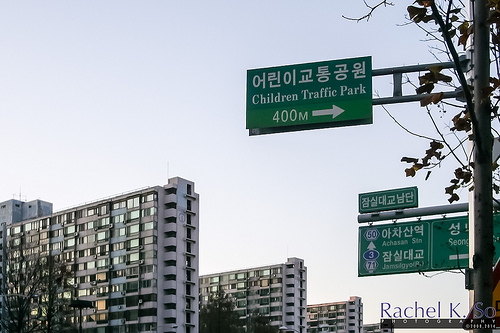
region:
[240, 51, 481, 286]
Green and white street signs.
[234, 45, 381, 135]
The sign is written in more than one language.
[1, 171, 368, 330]
Three buildings in a row.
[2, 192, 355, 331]
Windows on the buildings.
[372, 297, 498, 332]
The photographers name is listed in the bottom right corner.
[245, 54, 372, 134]
green sign with white writing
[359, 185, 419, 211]
green sign with white writing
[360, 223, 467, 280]
green sign with white writing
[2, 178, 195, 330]
tall white building with windows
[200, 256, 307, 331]
tall white building with windows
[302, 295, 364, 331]
tall white building with windows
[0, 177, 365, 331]
three tall white building with windows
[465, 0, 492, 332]
trunk of a skinny tree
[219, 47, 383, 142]
children traffic park sign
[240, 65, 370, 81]
chinese language on the sign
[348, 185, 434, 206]
chinese language on the sign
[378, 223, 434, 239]
chinese language on the sign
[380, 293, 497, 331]
rachel K so photography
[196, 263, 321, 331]
white apartment building in the distance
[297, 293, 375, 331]
white apartment building in the distance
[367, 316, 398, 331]
white apartment building in the distance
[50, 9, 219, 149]
beautiful blue sky for the day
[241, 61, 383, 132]
green and white highway sign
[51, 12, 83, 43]
white clouds in blue sky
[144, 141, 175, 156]
white clouds in blue sky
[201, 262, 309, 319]
white building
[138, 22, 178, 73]
white clouds in blue sky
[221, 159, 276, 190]
white clouds in blue sky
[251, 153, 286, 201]
white clouds in blue sky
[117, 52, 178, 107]
white clouds in blue sky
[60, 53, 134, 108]
white clouds in blue sky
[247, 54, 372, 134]
green and white sign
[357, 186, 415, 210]
sign is on a pole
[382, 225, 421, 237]
the writing is Asian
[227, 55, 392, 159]
a sign that is green in color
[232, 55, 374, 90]
writing that is written in korean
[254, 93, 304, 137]
a number that is white in color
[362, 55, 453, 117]
a pole that is grey in color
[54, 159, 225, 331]
an apartment building that is tall and white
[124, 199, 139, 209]
A window on a building.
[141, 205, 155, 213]
A window on a building.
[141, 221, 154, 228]
A window on a building.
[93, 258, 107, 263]
A window on a building.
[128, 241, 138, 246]
A window on a building.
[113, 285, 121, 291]
A window on a building.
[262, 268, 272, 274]
A window on a building.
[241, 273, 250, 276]
A window on a building.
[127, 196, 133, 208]
windown on large residential building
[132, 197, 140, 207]
windown on large residential building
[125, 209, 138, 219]
windown on large residential building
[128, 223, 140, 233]
windown on large residential building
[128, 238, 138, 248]
windown on large residential building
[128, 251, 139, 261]
windown on large residential building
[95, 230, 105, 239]
windown on large residential building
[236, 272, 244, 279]
windown on large residential building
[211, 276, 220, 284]
windown on large residential building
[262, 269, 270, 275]
windown on large residential building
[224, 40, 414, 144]
green and white sign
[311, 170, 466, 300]
sign with writing on it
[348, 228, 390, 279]
numbers on the sign